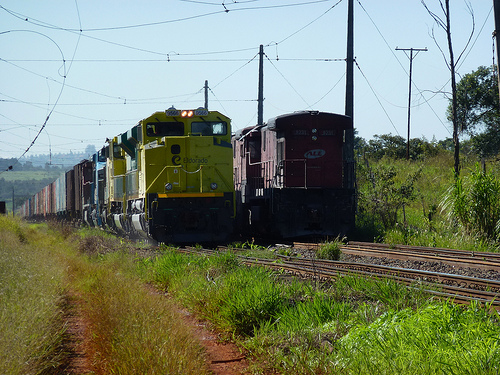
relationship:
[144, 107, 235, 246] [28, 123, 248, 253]
front of train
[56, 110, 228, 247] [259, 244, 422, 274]
train on tracks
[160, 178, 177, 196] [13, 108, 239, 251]
headlight of train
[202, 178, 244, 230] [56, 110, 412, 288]
headlight of train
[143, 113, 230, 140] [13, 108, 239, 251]
window on train